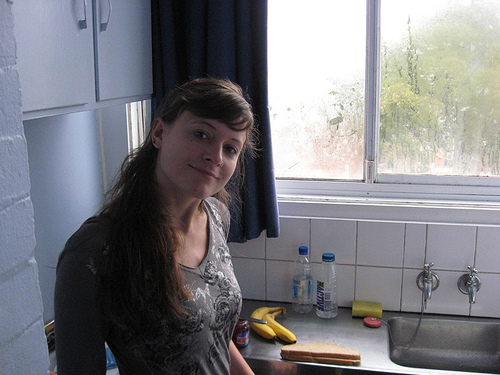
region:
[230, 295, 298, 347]
The bananas are yellow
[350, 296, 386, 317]
The sponge is yellow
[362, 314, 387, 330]
The drain plug is red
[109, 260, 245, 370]
Her shirt is black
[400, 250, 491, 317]
The sink has two faucets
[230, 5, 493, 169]
the drapes are open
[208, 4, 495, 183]
the window is closed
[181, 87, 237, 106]
Her hair is brown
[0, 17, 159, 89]
The cabinet is white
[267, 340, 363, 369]
The door stoppers are brown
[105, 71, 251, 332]
Woman has long brown hair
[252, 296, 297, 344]
Two bananas on a table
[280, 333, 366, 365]
A sandwich on the counter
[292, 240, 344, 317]
Two empty plastic bottles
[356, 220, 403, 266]
A white tile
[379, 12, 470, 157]
Streaks in the window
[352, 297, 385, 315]
A yellow sponge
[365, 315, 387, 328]
A red sink stopper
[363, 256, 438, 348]
Sink stopper chained to faucet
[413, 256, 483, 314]
Two silver faucets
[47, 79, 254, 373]
woman in kitchen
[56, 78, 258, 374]
lady wearing gray shirt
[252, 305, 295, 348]
pair of bananas on counter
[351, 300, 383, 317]
yellow wash sponge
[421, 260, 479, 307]
silver faucets for sink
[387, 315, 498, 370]
part of metal sink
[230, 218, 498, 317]
white tiled wall under window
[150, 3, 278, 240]
blue curtain hanging from window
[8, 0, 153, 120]
two white cabinet doors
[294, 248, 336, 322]
two clear water bottles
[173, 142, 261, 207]
a smile on the face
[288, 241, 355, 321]
two water bottles on counter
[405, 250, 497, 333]
two knobs for water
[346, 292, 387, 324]
a yellow sponge on counter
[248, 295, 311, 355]
two yellow bananas on counter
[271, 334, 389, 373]
a sandwich on the counter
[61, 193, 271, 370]
gray shirt on woman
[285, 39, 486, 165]
condensation on the window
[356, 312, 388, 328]
a red plug for the sink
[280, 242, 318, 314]
An empty water bottle.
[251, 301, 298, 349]
Two bright yellow bananas.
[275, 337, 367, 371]
Two pieces of unused bread.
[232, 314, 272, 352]
A container of nutella with a knife on the top.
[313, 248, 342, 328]
Another empty water bottle.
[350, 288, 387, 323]
A yellow and green sponge.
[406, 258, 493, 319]
Two vintage looking sink fosiets.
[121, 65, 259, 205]
A nice looking lady fake smiling for a photo.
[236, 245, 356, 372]
A variety of foods to eat.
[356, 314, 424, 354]
A water stopper for the sink.